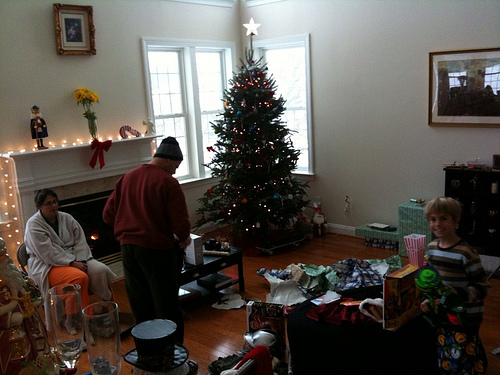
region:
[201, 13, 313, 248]
A christmas tree in the corner of the room.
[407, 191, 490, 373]
A smiling boy wearing pajamas.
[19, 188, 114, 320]
A seated woman in a robe and orange pants.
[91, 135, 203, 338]
A man in a sweater and cap, standing in the room.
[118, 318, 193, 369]
A black top hat.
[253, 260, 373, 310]
Discarded wrapping paper on the floor.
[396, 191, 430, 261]
An un-opened green present.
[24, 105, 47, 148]
A nutcracker doll on the fire place.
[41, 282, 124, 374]
Two empty glasses in the corner.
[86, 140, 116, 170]
A large, red bow hanging from the fire place.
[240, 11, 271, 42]
star on a christmas tree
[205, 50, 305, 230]
christmas tree next to window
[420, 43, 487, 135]
picture on a wall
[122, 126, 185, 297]
man wearing a hat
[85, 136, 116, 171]
bow on a fire place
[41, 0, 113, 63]
picture on a wall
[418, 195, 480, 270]
boy wearing a stripe shirt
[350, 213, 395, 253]
present next to wall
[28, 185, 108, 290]
woman wearing a robe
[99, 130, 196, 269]
man wearing maroon shirt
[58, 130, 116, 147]
Christmas lights on the fire place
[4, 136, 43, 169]
Christmas lights on the fire place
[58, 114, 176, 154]
Christmas lights on the fire place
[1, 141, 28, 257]
Christmas lights on the fire place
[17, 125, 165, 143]
Christmas lights on the fire place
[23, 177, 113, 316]
a woman sitting on a chair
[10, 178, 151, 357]
a woman sitting on a chair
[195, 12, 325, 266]
A decorated Christmas tree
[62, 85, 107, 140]
Yellow flowers in a vase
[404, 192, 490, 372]
A child holding a toy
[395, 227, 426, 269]
A popcorn container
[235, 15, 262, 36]
The star on top of the Christmas tree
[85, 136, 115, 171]
A red bow tied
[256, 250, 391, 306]
Ripped open wrapping paper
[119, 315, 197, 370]
A black tophat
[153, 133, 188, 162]
A black and grey ski cap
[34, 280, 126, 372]
Two glass champagne flutes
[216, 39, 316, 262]
green lit christmas tree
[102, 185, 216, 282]
red sweater on older man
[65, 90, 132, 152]
a vase of sunflowers on ledge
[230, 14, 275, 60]
white star on tree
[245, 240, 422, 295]
un wrapped wrapping paper on floor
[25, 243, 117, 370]
two glasses of champagne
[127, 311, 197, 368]
black top hat on table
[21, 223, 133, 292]
white sweater on woman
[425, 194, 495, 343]
young kid looking at camera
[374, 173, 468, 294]
green paper on gifts